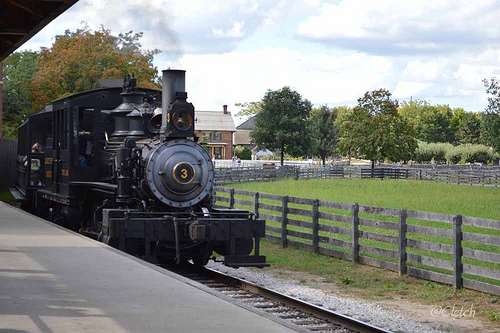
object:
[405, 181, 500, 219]
grass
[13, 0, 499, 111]
sky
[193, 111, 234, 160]
house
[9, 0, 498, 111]
clouds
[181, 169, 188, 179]
3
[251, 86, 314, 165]
tree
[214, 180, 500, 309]
field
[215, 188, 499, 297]
fence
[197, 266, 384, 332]
track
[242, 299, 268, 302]
part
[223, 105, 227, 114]
chimney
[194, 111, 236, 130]
roof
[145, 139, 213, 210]
front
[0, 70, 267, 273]
train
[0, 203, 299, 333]
sidewalk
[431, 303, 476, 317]
wording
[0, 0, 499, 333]
picture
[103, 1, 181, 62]
smoke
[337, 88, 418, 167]
tree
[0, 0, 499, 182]
background